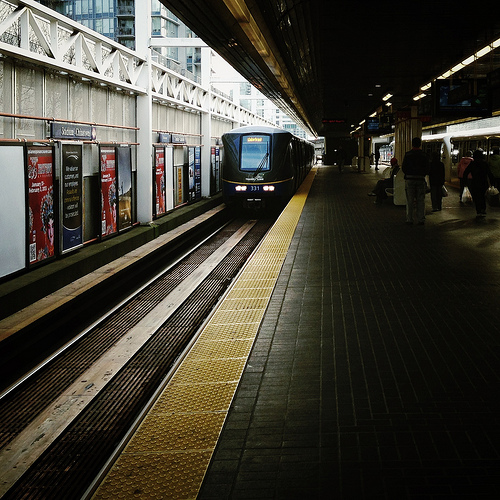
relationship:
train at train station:
[221, 125, 316, 220] [0, 0, 500, 500]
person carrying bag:
[463, 147, 496, 218] [459, 183, 472, 205]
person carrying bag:
[463, 147, 496, 218] [485, 184, 498, 198]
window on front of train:
[238, 132, 270, 172] [213, 121, 316, 225]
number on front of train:
[249, 179, 262, 191] [221, 125, 316, 220]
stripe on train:
[219, 174, 292, 188] [220, 122, 317, 221]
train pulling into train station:
[221, 125, 316, 220] [0, 0, 500, 500]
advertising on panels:
[11, 119, 118, 254] [1, 125, 191, 263]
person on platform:
[401, 136, 430, 226] [284, 191, 485, 394]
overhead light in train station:
[419, 37, 499, 93] [0, 0, 499, 499]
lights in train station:
[412, 92, 427, 103] [0, 0, 499, 499]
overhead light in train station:
[378, 88, 393, 103] [0, 0, 499, 499]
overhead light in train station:
[356, 100, 392, 127] [0, 0, 499, 499]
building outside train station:
[68, 0, 209, 71] [226, 110, 498, 499]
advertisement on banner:
[118, 124, 188, 230] [119, 137, 182, 222]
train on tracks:
[221, 125, 316, 220] [3, 210, 272, 339]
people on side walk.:
[382, 141, 491, 226] [233, 122, 490, 339]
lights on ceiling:
[426, 39, 497, 96] [175, 2, 496, 129]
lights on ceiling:
[349, 90, 392, 133] [175, 2, 496, 129]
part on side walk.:
[86, 157, 323, 499] [197, 165, 500, 500]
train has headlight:
[221, 125, 316, 220] [233, 181, 253, 198]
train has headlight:
[218, 123, 314, 204] [268, 185, 274, 192]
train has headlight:
[218, 123, 314, 204] [263, 185, 268, 190]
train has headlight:
[218, 123, 314, 204] [241, 185, 246, 190]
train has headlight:
[218, 123, 314, 204] [235, 185, 242, 190]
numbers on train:
[239, 175, 268, 196] [167, 69, 368, 294]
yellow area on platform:
[213, 220, 293, 341] [77, 173, 382, 497]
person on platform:
[458, 140, 492, 220] [90, 158, 499, 498]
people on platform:
[427, 150, 446, 213] [90, 158, 499, 498]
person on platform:
[405, 132, 432, 227] [90, 158, 499, 498]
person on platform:
[456, 148, 480, 189] [90, 158, 499, 498]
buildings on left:
[113, 20, 249, 145] [84, 4, 194, 205]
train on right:
[364, 116, 499, 175] [444, 94, 491, 214]